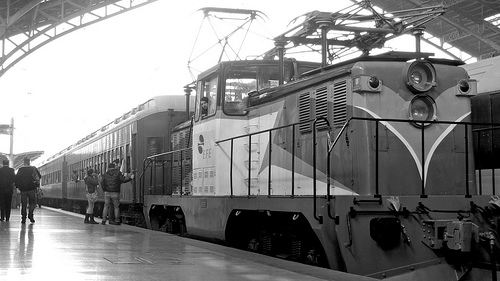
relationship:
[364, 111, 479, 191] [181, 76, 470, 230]
v on train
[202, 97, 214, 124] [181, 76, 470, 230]
passenger on train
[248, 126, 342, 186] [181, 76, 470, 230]
rail on train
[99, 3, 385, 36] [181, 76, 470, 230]
beams over train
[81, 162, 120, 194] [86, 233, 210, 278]
people on platform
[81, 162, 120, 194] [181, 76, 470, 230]
people next to train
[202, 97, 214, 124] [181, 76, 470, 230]
passenger in train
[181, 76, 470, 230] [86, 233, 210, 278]
train on platform